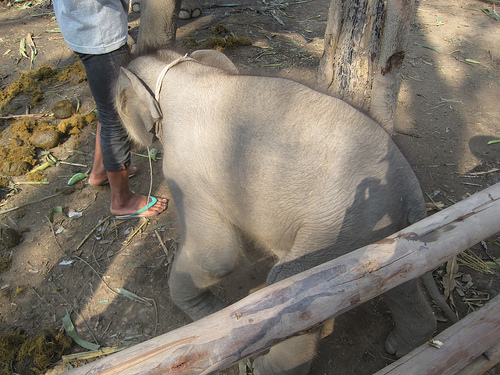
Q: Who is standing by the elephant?
A: A man.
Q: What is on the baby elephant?
A: A collar.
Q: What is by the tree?
A: A baby elephant.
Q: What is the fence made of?
A: Wood.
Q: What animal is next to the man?
A: A baby elephant.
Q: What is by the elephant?
A: A tree.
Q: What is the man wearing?
A: A shirt and shorts.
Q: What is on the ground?
A: Sticks and rocks.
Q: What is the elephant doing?
A: Standing.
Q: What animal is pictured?
A: Elephant.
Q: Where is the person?
A: Beside the elephant.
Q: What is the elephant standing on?
A: Dirt.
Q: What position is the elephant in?
A: Standing.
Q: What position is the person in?
A: Standing.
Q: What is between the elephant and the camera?
A: Fence.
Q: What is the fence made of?
A: Wood.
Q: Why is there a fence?
A: To contain the elephant.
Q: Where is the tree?
A: Next to the elephant.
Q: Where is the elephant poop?
A: Behind the person.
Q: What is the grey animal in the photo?
A: Elephant.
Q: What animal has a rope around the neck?
A: Elephant.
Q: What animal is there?
A: Elephant.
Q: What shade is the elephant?
A: Gray.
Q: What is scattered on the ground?
A: Leaves.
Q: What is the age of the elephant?
A: Baby.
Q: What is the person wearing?
A: Jeans.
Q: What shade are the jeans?
A: Blue.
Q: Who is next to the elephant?
A: Child.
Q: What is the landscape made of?
A: Dirt.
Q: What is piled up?
A: Excrement.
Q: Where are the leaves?
A: Ground.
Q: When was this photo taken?
A: During the day.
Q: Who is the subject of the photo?
A: The elephant.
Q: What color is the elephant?
A: Gray.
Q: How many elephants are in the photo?
A: 1.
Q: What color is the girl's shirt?
A: Blue.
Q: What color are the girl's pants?
A: Gray.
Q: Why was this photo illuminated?
A: Sunlight.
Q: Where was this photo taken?
A: In a zoo.